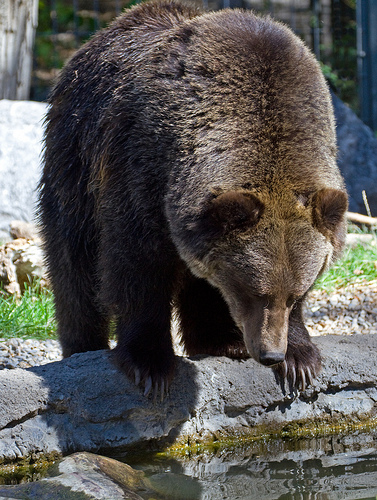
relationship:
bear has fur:
[41, 6, 344, 402] [83, 39, 298, 149]